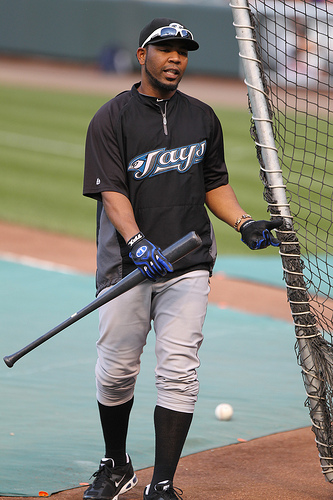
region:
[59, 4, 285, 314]
black man in Jays baseball uniform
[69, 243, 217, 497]
gray baseball pants rolled up to knees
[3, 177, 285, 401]
blue and black batting gloves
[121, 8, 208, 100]
man with white sunglasses on his black hat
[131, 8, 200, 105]
man wearing black baseball cap with white sunglasses on them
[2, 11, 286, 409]
man holding black baseball bat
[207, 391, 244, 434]
white baseball on green tarp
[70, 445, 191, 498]
black and white nikes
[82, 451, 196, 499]
Black and white sneakers on a man.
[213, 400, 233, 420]
A baseball laying on the ground.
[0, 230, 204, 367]
A black baseball bat.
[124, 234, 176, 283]
The black and blue glove of a baseball player.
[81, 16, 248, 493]
Man in a baseball uniform.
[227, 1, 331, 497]
A net on a baseball field.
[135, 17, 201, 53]
Sunglasses on a baseball hat.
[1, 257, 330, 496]
Green tarp on a baseball field.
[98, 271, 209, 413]
Grey uniform pants of a ball player.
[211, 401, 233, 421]
White baseball on the ground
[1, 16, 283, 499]
Man holding a baseball bat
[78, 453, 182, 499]
Black and white Nike shoes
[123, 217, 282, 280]
Black and blue gloves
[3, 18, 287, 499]
Man wearing a black jersey and gray pants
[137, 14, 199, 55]
Black hat with silver glasses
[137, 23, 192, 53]
White sunglasses resting on a hat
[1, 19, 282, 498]
Baseball player on a baseball field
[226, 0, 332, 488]
Net on a metal pole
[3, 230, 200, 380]
Black metal baseball bat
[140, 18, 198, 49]
black hat on head of man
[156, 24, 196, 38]
\white sunglasses on hat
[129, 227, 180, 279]
blue and black glove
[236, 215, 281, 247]
blue and black glove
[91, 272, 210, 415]
grey shorts on legs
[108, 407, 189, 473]
black socks on legs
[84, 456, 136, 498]
white and black cleats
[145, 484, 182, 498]
white and black cleat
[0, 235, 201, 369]
black bat in hand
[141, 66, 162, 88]
black beard on face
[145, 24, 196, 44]
SUNGLASSES OVER A HAT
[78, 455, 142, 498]
A BLACK AND WHITE ATHLETIC SHOE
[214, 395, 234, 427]
A BASEBALL ON THE GROUND.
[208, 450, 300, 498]
BROWN DIRT ON THE GROUND.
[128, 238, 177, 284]
A BLACK AND BLUE GLOVE.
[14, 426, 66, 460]
A GREEN TARP OVER THE GROUND.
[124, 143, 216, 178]
A JAYS LOGO ON A JERSEY.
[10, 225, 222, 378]
A BLACK BASEBALL BAT.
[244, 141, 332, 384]
A LARGE NET NEAR THE PLAYER.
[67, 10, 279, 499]
A PLAYER WALKING TO THE EDGE OF THE FIELD.